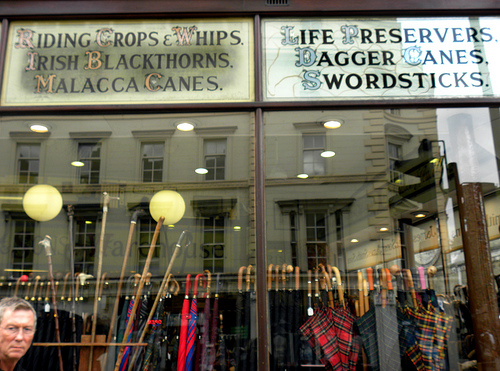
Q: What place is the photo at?
A: It is at the store.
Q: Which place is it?
A: It is a store.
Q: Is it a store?
A: Yes, it is a store.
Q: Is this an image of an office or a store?
A: It is showing a store.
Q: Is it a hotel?
A: No, it is a store.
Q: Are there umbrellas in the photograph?
A: Yes, there are umbrellas.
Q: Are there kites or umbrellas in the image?
A: Yes, there are umbrellas.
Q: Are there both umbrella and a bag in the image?
A: No, there are umbrellas but no bags.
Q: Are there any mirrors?
A: No, there are no mirrors.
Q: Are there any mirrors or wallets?
A: No, there are no mirrors or wallets.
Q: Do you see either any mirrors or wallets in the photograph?
A: No, there are no mirrors or wallets.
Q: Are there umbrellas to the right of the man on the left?
A: Yes, there are umbrellas to the right of the man.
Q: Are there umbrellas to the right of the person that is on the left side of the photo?
A: Yes, there are umbrellas to the right of the man.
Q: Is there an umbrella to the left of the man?
A: No, the umbrellas are to the right of the man.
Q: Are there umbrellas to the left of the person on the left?
A: No, the umbrellas are to the right of the man.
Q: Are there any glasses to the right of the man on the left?
A: No, there are umbrellas to the right of the man.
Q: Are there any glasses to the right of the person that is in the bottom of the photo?
A: No, there are umbrellas to the right of the man.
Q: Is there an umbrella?
A: Yes, there is an umbrella.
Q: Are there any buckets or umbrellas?
A: Yes, there is an umbrella.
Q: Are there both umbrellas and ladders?
A: No, there is an umbrella but no ladders.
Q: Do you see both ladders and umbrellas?
A: No, there is an umbrella but no ladders.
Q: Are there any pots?
A: No, there are no pots.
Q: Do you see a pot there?
A: No, there are no pots.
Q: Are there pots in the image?
A: No, there are no pots.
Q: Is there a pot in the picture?
A: No, there are no pots.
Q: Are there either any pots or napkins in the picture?
A: No, there are no pots or napkins.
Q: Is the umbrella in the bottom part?
A: Yes, the umbrella is in the bottom of the image.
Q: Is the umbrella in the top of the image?
A: No, the umbrella is in the bottom of the image.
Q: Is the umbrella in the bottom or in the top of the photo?
A: The umbrella is in the bottom of the image.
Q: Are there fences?
A: No, there are no fences.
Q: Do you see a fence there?
A: No, there are no fences.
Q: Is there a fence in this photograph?
A: No, there are no fences.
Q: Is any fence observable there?
A: No, there are no fences.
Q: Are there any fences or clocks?
A: No, there are no fences or clocks.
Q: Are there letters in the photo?
A: Yes, there are letters.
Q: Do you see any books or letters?
A: Yes, there are letters.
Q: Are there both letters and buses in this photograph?
A: No, there are letters but no buses.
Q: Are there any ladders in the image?
A: No, there are no ladders.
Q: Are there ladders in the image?
A: No, there are no ladders.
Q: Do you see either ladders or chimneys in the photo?
A: No, there are no ladders or chimneys.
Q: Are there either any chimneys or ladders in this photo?
A: No, there are no ladders or chimneys.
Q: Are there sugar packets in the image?
A: No, there are no sugar packets.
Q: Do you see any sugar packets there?
A: No, there are no sugar packets.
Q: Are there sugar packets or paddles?
A: No, there are no sugar packets or paddles.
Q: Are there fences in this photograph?
A: No, there are no fences.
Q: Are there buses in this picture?
A: No, there are no buses.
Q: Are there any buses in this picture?
A: No, there are no buses.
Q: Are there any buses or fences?
A: No, there are no buses or fences.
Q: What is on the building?
A: The sign is on the building.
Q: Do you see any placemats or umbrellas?
A: Yes, there is an umbrella.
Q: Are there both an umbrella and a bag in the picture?
A: No, there is an umbrella but no bags.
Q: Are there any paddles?
A: No, there are no paddles.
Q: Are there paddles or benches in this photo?
A: No, there are no paddles or benches.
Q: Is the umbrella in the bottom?
A: Yes, the umbrella is in the bottom of the image.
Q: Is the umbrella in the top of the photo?
A: No, the umbrella is in the bottom of the image.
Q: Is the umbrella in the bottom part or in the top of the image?
A: The umbrella is in the bottom of the image.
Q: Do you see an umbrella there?
A: Yes, there is an umbrella.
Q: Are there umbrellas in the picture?
A: Yes, there is an umbrella.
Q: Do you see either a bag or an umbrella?
A: Yes, there is an umbrella.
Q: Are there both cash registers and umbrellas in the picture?
A: No, there is an umbrella but no cash registers.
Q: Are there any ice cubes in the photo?
A: No, there are no ice cubes.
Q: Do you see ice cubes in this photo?
A: No, there are no ice cubes.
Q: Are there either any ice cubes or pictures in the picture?
A: No, there are no ice cubes or pictures.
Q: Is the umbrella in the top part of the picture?
A: No, the umbrella is in the bottom of the image.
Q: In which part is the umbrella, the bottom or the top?
A: The umbrella is in the bottom of the image.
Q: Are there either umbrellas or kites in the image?
A: Yes, there is an umbrella.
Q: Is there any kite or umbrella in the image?
A: Yes, there is an umbrella.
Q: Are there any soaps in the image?
A: No, there are no soaps.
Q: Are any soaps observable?
A: No, there are no soaps.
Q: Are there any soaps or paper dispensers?
A: No, there are no soaps or paper dispensers.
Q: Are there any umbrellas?
A: Yes, there is an umbrella.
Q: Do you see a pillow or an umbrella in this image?
A: Yes, there is an umbrella.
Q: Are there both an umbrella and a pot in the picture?
A: No, there is an umbrella but no pots.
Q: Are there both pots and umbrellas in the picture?
A: No, there is an umbrella but no pots.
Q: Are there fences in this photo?
A: No, there are no fences.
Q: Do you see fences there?
A: No, there are no fences.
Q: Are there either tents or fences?
A: No, there are no fences or tents.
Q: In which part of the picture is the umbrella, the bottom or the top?
A: The umbrella is in the bottom of the image.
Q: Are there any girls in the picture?
A: No, there are no girls.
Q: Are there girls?
A: No, there are no girls.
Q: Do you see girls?
A: No, there are no girls.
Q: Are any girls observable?
A: No, there are no girls.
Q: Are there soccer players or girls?
A: No, there are no girls or soccer players.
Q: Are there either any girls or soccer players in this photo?
A: No, there are no girls or soccer players.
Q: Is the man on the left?
A: Yes, the man is on the left of the image.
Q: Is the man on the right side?
A: No, the man is on the left of the image.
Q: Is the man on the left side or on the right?
A: The man is on the left of the image.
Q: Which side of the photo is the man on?
A: The man is on the left of the image.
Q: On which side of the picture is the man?
A: The man is on the left of the image.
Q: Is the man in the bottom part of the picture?
A: Yes, the man is in the bottom of the image.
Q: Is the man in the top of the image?
A: No, the man is in the bottom of the image.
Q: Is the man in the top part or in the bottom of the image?
A: The man is in the bottom of the image.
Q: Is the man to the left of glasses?
A: No, the man is to the left of the umbrellas.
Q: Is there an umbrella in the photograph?
A: Yes, there is an umbrella.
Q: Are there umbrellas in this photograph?
A: Yes, there is an umbrella.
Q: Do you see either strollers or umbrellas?
A: Yes, there is an umbrella.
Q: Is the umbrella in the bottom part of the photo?
A: Yes, the umbrella is in the bottom of the image.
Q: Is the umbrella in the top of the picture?
A: No, the umbrella is in the bottom of the image.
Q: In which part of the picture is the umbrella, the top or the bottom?
A: The umbrella is in the bottom of the image.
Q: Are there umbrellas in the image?
A: Yes, there is an umbrella.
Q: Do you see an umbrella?
A: Yes, there is an umbrella.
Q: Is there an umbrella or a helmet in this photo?
A: Yes, there is an umbrella.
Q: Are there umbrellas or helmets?
A: Yes, there is an umbrella.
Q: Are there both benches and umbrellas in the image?
A: No, there is an umbrella but no benches.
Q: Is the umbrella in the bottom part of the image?
A: Yes, the umbrella is in the bottom of the image.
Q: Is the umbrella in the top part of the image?
A: No, the umbrella is in the bottom of the image.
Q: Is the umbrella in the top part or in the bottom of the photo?
A: The umbrella is in the bottom of the image.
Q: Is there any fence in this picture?
A: No, there are no fences.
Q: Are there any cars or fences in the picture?
A: No, there are no fences or cars.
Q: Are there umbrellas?
A: Yes, there is an umbrella.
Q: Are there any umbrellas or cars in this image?
A: Yes, there is an umbrella.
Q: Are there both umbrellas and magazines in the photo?
A: No, there is an umbrella but no magazines.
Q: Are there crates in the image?
A: No, there are no crates.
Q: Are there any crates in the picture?
A: No, there are no crates.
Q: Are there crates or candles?
A: No, there are no crates or candles.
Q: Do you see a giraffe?
A: Yes, there is a giraffe.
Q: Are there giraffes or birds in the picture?
A: Yes, there is a giraffe.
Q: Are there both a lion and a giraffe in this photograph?
A: No, there is a giraffe but no lions.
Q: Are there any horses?
A: No, there are no horses.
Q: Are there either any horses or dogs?
A: No, there are no horses or dogs.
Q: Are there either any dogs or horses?
A: No, there are no horses or dogs.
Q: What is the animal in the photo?
A: The animal is a giraffe.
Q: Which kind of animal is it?
A: The animal is a giraffe.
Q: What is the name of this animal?
A: This is a giraffe.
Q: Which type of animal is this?
A: This is a giraffe.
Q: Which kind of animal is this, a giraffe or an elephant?
A: This is a giraffe.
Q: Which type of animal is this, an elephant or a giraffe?
A: This is a giraffe.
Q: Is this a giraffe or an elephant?
A: This is a giraffe.